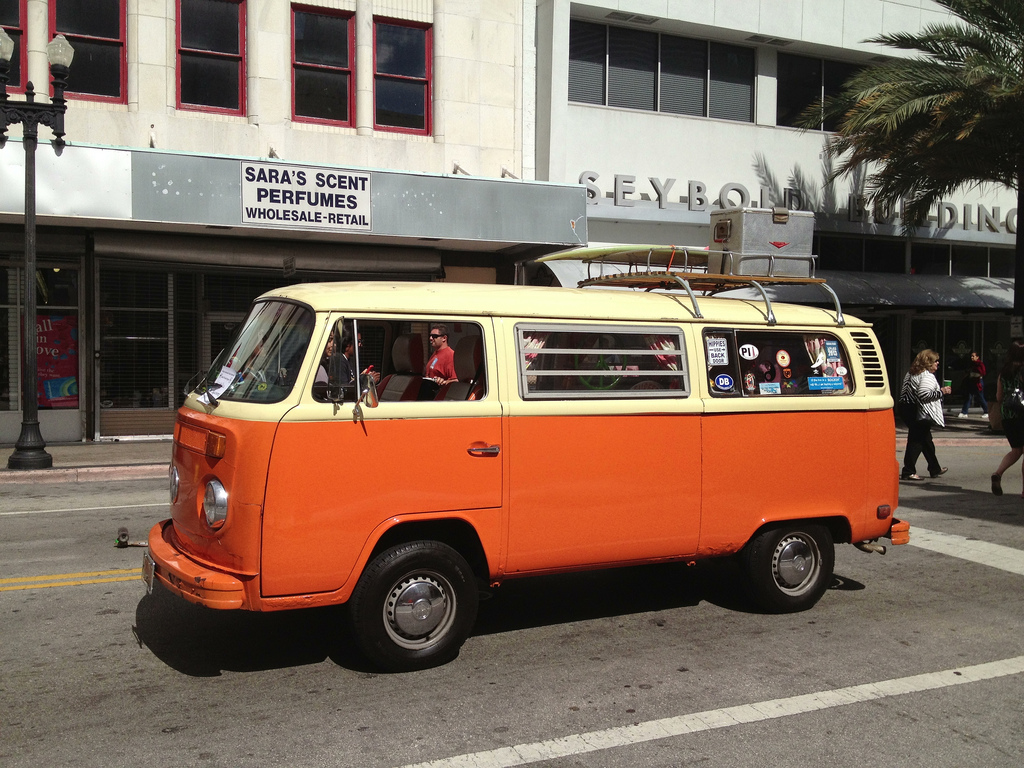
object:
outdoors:
[2, 4, 1021, 766]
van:
[114, 246, 909, 672]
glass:
[293, 64, 349, 130]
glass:
[359, 317, 476, 403]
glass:
[310, 321, 355, 401]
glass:
[511, 328, 687, 398]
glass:
[702, 330, 857, 398]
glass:
[434, 380, 483, 433]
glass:
[375, 20, 430, 78]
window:
[567, 2, 757, 118]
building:
[540, 0, 1020, 434]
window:
[562, 24, 757, 127]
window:
[770, 58, 861, 128]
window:
[372, 16, 431, 134]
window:
[290, 0, 343, 70]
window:
[167, 0, 242, 116]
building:
[0, 0, 589, 450]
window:
[99, 272, 166, 411]